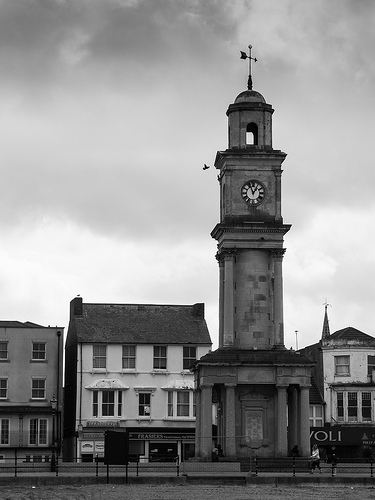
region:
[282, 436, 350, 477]
the children are playing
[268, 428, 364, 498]
the children are playing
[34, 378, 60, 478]
a black lamp post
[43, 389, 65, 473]
a black lamp post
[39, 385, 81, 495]
a black lamp post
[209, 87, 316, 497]
a tall clock tower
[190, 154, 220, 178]
the bird is flying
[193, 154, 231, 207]
the bird is flying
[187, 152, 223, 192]
the bird is flying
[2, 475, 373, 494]
gray brick sidewalk in city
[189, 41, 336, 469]
stone clock tower in city with weather vane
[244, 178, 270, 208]
round white clockface in tower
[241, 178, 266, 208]
round white clcokface with black hands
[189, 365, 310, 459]
grey stone pillars under tower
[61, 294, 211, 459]
white building with two canopied windows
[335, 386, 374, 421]
bay window on white building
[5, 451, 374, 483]
blcl metal fence running along street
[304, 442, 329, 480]
woman walking near bench in white shirt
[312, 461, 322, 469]
woman wearing black pants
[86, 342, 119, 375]
Large window on a building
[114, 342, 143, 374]
Large window on a building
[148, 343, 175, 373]
Large window on a building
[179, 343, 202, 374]
Large window on a building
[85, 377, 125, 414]
Large window on a building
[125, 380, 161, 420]
Large window on a building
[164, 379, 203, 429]
Large window on a building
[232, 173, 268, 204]
White and black slock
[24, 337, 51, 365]
Large window on a building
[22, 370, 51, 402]
Large window on a building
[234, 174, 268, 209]
a clock on a clock tower.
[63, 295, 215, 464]
a multi story white home.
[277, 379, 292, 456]
a pillar in a clock tower.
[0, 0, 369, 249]
A large gray cloud in a sky.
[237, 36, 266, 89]
a large metal weather vane.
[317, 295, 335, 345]
A christmas decoration on a roof.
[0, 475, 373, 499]
A road near a clock tower.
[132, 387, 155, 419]
a window on a building.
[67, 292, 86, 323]
A chimney on a building.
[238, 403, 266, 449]
a door on a clock tower.